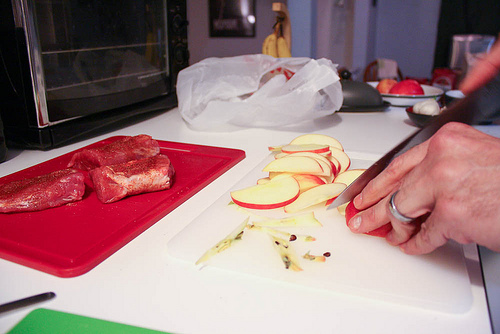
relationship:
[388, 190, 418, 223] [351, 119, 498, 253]
ring on hand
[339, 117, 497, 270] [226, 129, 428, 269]
person holding apple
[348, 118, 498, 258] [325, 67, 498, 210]
person holding knife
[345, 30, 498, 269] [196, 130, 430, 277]
man slicing apples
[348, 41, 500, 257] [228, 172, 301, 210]
man slicing apple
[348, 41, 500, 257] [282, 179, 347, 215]
man slicing apple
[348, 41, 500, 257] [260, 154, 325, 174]
man slicing apple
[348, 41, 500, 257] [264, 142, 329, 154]
man slicing apple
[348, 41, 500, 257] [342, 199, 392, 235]
man slicing apple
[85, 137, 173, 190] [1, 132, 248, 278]
meat on red tray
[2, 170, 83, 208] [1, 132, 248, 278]
meat on red tray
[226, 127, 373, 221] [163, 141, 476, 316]
apples on cutting board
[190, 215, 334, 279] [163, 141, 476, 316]
apple seeds on cutting board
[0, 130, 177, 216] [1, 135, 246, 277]
meat on cutting board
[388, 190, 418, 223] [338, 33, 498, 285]
ring on person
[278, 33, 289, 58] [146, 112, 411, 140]
banana on counter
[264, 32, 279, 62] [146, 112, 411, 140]
banana on counter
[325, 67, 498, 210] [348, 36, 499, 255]
knife on person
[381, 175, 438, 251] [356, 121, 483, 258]
ring on left hand